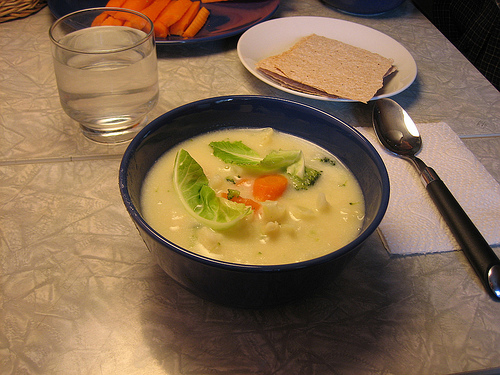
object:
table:
[0, 11, 499, 375]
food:
[141, 125, 369, 266]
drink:
[46, 6, 157, 133]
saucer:
[235, 11, 423, 106]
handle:
[430, 184, 496, 299]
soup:
[145, 123, 365, 264]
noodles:
[265, 209, 301, 234]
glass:
[101, 9, 141, 26]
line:
[84, 270, 131, 279]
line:
[87, 230, 124, 237]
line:
[97, 270, 130, 281]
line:
[78, 252, 127, 264]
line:
[10, 265, 53, 277]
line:
[172, 344, 186, 372]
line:
[5, 150, 62, 171]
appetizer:
[169, 147, 256, 232]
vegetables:
[174, 144, 320, 239]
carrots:
[249, 173, 287, 202]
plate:
[114, 91, 392, 308]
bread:
[253, 30, 399, 108]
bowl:
[236, 15, 419, 106]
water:
[52, 22, 158, 133]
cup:
[47, 6, 158, 144]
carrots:
[89, 0, 198, 35]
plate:
[46, 3, 283, 50]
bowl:
[114, 91, 394, 309]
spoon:
[354, 115, 500, 260]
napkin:
[354, 120, 499, 256]